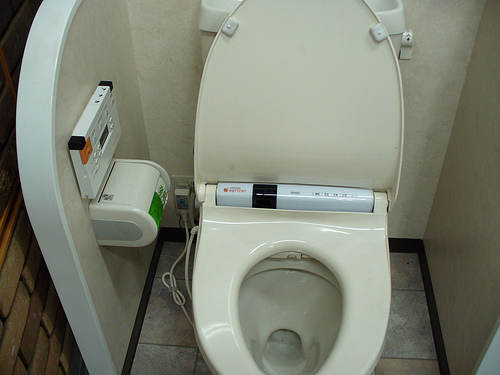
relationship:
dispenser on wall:
[94, 179, 169, 242] [113, 28, 189, 74]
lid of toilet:
[276, 17, 384, 43] [173, 180, 381, 353]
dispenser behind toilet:
[88, 154, 172, 249] [173, 180, 381, 353]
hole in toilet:
[261, 323, 303, 360] [173, 180, 381, 353]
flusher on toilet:
[402, 26, 425, 61] [173, 180, 381, 353]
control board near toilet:
[59, 98, 123, 172] [173, 180, 381, 353]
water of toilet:
[242, 292, 245, 293] [173, 180, 381, 353]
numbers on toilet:
[216, 185, 241, 196] [173, 180, 381, 353]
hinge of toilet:
[367, 191, 392, 221] [173, 180, 381, 353]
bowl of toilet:
[261, 301, 333, 352] [173, 180, 381, 353]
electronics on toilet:
[237, 189, 306, 206] [173, 180, 381, 353]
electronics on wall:
[237, 189, 306, 206] [113, 28, 189, 74]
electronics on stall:
[237, 189, 306, 206] [33, 31, 124, 57]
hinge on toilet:
[367, 191, 392, 221] [173, 180, 381, 353]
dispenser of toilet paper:
[94, 179, 169, 242] [115, 222, 164, 255]